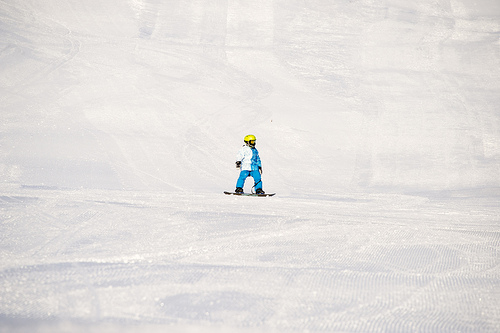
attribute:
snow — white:
[295, 59, 457, 171]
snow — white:
[0, 0, 224, 330]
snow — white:
[225, 0, 283, 124]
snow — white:
[219, 194, 289, 331]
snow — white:
[314, 2, 494, 329]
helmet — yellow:
[240, 135, 255, 145]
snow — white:
[50, 54, 121, 152]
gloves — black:
[235, 163, 241, 168]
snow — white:
[22, 204, 311, 294]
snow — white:
[6, 7, 499, 131]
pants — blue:
[231, 158, 270, 182]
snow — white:
[1, 4, 495, 330]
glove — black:
[224, 154, 240, 184]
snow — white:
[160, 117, 364, 262]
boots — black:
[221, 184, 265, 224]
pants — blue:
[234, 173, 265, 229]